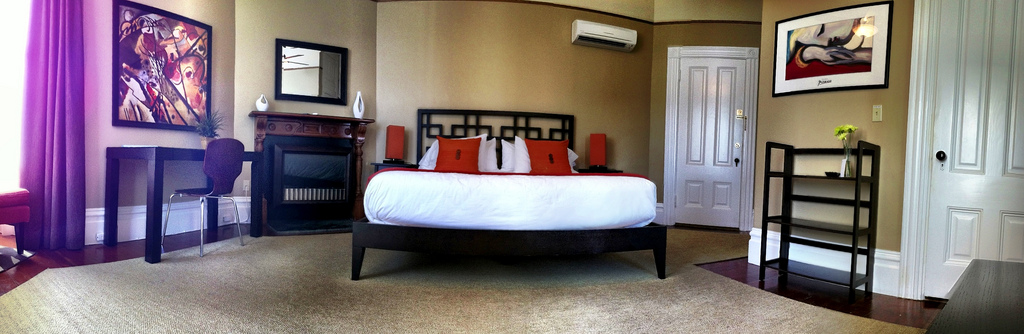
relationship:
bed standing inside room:
[351, 108, 671, 282] [5, 5, 993, 328]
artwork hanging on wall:
[772, 4, 893, 93] [750, 3, 915, 252]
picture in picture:
[112, 2, 210, 133] [112, 2, 210, 133]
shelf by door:
[757, 140, 878, 296] [667, 48, 753, 230]